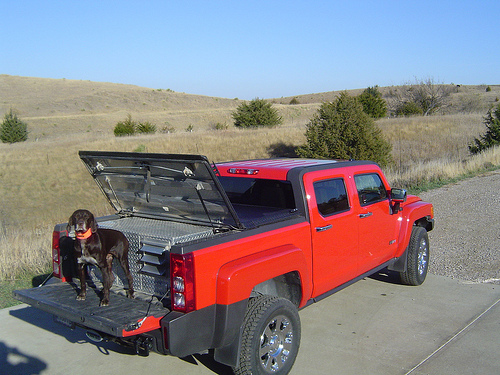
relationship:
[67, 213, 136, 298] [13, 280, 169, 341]
dog on tailgate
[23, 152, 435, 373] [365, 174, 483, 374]
truck along road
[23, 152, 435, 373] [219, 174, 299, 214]
truck has window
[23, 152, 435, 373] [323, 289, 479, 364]
truck on concrete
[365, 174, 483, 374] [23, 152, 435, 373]
road in front of truck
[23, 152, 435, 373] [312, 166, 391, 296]
truck has doors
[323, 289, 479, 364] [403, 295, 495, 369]
concrete has crack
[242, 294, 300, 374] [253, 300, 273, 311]
tire has grooves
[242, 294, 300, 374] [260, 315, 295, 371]
tire has rims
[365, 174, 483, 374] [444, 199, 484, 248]
road has gravel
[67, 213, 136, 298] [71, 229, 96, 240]
dog has collar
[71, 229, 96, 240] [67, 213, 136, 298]
collar on dog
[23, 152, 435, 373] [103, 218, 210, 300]
truck has tool box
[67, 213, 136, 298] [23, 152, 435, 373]
dog on truck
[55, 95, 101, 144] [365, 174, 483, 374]
grass near road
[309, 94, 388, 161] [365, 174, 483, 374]
tree near road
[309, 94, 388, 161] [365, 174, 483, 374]
tree along road